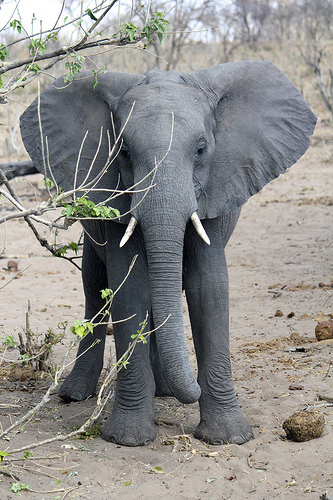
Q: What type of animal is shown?
A: Elephant.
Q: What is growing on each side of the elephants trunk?
A: Tusks.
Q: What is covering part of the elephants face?
A: Tree branches.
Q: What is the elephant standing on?
A: Sand.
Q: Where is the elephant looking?
A: At the camera.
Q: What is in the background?
A: Trees.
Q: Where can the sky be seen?
A: Top middle of the image.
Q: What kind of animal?
A: Elephant.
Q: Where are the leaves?
A: On the tree.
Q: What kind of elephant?
A: Baby.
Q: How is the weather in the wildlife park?
A: Cloudy and fair.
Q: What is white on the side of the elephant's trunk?
A: Tusks.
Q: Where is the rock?
A: On the ground.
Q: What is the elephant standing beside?
A: A tree.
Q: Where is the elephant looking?
A: Towards the ground.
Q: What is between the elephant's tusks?
A: Trunk.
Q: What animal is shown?
A: Elephant.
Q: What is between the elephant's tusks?
A: Trunk.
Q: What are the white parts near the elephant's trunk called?
A: Tusks.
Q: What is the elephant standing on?
A: Sand.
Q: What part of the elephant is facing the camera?
A: Front.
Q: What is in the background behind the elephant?
A: Trees.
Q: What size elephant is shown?
A: Small.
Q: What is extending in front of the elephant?
A: Branches.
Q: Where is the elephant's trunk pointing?
A: Ground.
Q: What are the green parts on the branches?
A: Leaves.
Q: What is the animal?
A: Elephant.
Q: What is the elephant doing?
A: Standing.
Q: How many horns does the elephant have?
A: Two.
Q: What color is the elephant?
A: Gray.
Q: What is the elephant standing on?
A: Sand.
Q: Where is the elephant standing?
A: By a tree.